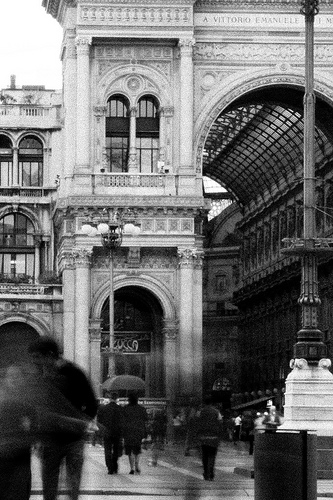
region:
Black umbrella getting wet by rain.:
[204, 374, 224, 425]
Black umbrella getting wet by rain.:
[115, 450, 133, 464]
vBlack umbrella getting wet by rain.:
[71, 195, 144, 230]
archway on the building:
[83, 273, 193, 426]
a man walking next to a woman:
[95, 390, 151, 484]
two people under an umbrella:
[94, 367, 162, 478]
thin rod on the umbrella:
[121, 388, 129, 405]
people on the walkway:
[4, 323, 263, 498]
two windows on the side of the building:
[98, 90, 162, 173]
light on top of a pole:
[96, 207, 131, 249]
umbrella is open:
[99, 372, 145, 401]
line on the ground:
[147, 454, 206, 483]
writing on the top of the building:
[199, 10, 332, 32]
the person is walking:
[184, 397, 219, 481]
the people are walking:
[100, 382, 149, 472]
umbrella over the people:
[107, 370, 147, 402]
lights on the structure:
[58, 212, 142, 245]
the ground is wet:
[76, 466, 129, 491]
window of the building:
[18, 263, 48, 276]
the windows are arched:
[101, 83, 166, 168]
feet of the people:
[96, 464, 146, 482]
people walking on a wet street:
[0, 333, 250, 493]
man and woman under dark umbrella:
[92, 367, 141, 469]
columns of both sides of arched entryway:
[51, 233, 192, 392]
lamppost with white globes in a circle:
[77, 207, 136, 368]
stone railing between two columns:
[67, 24, 197, 188]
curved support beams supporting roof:
[189, 3, 323, 204]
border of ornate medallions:
[226, 184, 296, 278]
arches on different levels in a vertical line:
[0, 119, 54, 337]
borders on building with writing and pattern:
[192, 10, 326, 63]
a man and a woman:
[99, 393, 150, 480]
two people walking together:
[96, 391, 151, 475]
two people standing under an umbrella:
[96, 371, 158, 480]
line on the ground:
[154, 455, 203, 478]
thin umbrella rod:
[122, 388, 129, 407]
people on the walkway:
[1, 316, 241, 499]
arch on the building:
[92, 274, 184, 409]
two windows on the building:
[98, 92, 163, 172]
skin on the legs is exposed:
[126, 448, 141, 468]